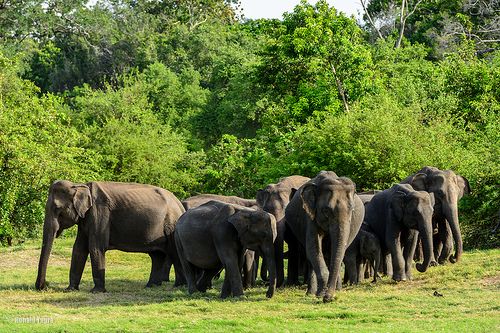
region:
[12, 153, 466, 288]
herd of elephants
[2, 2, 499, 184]
greenery behind elephants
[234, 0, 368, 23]
sky peaking out from trees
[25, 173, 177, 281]
elephant turned to the side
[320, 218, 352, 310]
trunk of middle elephant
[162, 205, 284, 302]
small elephant in front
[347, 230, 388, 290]
baby elephant touching bigger elephant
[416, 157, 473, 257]
elephant furtherest to the right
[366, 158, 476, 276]
two elephants on the right side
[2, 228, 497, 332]
grass the elephants are standing on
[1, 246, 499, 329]
The grass is green.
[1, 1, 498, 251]
The trees are green.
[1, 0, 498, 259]
Trees are in the background.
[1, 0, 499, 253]
The trees have leaves.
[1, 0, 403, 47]
The sky is blue.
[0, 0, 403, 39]
The sky is clear.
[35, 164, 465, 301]
The elephants are gray.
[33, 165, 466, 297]
The elephants are in a group.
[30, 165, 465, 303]
The elephants are large.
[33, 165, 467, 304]
The elephants are walking.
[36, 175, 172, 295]
this is an elephant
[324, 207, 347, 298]
this is the trunk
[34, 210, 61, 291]
the trunk is long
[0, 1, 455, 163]
this is a forest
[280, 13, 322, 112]
this is a tree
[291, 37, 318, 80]
the leaves are green in color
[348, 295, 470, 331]
this is a grass area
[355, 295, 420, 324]
the grass is green in color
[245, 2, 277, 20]
this is the sky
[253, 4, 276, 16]
the sky is blue in color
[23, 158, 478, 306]
elephants standing on grass and soil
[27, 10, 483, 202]
trees growing in back of elephants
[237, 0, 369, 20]
clear and bright sky behind trees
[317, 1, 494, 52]
bare branches above leaves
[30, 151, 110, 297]
elephants with trunk touching ground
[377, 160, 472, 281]
side by side elephants with curled trunks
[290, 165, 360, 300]
elephant with trunk slanted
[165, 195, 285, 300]
small elephant with light across head and body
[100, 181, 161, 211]
slanted markings on side of body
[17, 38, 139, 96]
dark oval in center of trees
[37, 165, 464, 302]
Herd of elephants standing on grass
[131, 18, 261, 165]
Green trees behind elephants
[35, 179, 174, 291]
Elephant grazing on green grass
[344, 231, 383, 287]
Baby elephant hidden in shadow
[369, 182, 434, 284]
Elephant with curved trunk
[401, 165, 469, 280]
Two elephants with curved trunks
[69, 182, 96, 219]
Grey ear of elephant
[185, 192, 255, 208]
Elephant partially behind another elephant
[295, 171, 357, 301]
Face and trunk of grey elephant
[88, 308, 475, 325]
Green grass in the foreground